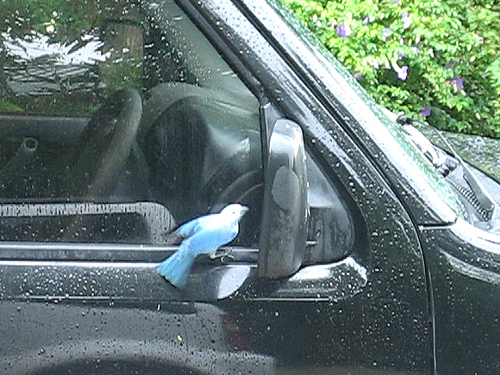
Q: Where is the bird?
A: On car window ledge.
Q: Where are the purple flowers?
A: Behind the car on bushes.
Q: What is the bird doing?
A: Looking in the mirror.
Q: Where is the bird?
A: On the side of the car.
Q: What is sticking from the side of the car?
A: Mirror.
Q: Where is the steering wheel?
A: Inside the car.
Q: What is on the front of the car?
A: Windshield wiper.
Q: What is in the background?
A: Bushes.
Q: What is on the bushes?
A: Flowers.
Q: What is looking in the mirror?
A: A bird.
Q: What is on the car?
A: Water.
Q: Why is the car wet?
A: Rain.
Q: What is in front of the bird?
A: The mirror.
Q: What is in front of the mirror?
A: A bird.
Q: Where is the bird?
A: On the side of the car.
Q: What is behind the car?
A: Leaves.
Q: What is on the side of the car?
A: A white bird.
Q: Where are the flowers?
A: On the bush behind the car.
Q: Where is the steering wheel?
A: Inside the car.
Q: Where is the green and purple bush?
A: Behind the car.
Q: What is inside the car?
A: A black steering wheel.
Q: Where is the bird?
A: On the vehicle.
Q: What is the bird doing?
A: Looking in the mirror.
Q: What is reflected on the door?
A: A white vehicle.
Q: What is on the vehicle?
A: A bird.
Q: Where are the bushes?
A: Left of the vehicle.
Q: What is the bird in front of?
A: The mirror.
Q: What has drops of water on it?
A: The vehicle.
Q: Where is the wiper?
A: On the front window.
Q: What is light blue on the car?
A: A bird.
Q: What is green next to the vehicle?
A: Bushes.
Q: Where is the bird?
A: On the window sill.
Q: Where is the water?
A: On the car.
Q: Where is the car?
A: Next to the trees.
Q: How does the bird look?
A: Small and blue.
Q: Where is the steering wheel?
A: Inside the car.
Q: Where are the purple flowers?
A: On the trees.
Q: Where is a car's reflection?
A: In the window.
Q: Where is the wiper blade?
A: On the windshield.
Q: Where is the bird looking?
A: Side mirror.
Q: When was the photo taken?
A: Daytime.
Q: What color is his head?
A: White.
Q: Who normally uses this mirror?
A: The driver.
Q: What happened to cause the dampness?
A: It rained.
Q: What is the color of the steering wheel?
A: Gray.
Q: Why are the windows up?
A: To keep it dry.